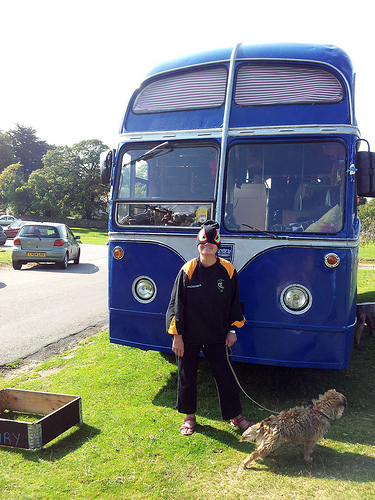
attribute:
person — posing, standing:
[165, 223, 247, 438]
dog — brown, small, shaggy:
[241, 388, 348, 471]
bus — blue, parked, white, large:
[106, 38, 374, 372]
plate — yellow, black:
[26, 250, 50, 259]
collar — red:
[309, 407, 332, 422]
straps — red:
[181, 418, 199, 431]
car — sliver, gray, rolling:
[13, 220, 81, 271]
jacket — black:
[168, 258, 245, 339]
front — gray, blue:
[115, 64, 346, 368]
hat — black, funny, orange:
[197, 222, 220, 249]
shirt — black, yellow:
[165, 260, 250, 333]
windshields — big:
[115, 143, 348, 237]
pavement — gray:
[0, 245, 111, 369]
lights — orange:
[112, 245, 338, 268]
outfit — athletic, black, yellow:
[166, 256, 245, 424]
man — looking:
[354, 299, 372, 345]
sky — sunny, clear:
[0, 0, 374, 152]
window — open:
[118, 144, 218, 232]